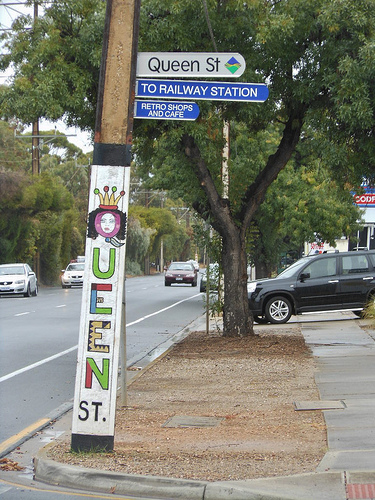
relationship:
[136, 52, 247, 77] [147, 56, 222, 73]
sign with lettering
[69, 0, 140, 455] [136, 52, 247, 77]
pole with a sign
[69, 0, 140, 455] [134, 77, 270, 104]
pole with a sign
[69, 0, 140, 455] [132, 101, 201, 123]
pole with a sign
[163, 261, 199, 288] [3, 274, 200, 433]
car driving up road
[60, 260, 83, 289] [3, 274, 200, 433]
car driving up road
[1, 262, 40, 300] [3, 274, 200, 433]
car driving up road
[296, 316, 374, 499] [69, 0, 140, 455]
sidewalk beside sign post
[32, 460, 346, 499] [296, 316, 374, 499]
gray curb of sidewalk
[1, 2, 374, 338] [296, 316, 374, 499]
tree planted on sidewalk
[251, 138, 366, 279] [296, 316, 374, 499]
tree planted on sidewalk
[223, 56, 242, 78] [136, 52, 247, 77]
diamond shape on sign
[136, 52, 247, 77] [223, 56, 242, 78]
sign with design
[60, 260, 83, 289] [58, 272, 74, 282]
white car with headlight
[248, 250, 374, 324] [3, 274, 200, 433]
suv pulling onto street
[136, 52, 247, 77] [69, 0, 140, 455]
sign on a pole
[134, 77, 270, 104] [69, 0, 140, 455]
sign on side of pole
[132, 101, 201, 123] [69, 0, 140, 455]
sign on side of pole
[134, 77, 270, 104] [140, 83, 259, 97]
sign with "to railway station"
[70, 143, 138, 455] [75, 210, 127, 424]
white sign with words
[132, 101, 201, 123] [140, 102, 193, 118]
sign with "retro shops and .."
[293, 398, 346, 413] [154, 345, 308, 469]
square in dirt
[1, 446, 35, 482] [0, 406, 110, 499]
leaves at side of road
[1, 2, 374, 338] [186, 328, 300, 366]
tree growing in gravel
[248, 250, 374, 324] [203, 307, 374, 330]
suv pulling out of driveway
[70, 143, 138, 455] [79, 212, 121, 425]
sign for queen st.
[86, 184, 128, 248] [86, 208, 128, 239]
queen with hair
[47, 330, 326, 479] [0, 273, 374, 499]
gravel area between sidewalk and street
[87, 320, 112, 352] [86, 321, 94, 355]
letter e with stripes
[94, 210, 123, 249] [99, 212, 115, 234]
letter q with a face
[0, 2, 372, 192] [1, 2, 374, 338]
leaves on tree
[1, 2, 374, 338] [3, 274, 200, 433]
tree next to a road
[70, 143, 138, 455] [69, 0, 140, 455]
painting on a post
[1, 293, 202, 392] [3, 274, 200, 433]
line on road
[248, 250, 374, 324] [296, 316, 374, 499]
vehicle on a side walk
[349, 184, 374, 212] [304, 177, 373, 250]
sign on front of building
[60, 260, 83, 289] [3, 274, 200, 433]
car on road